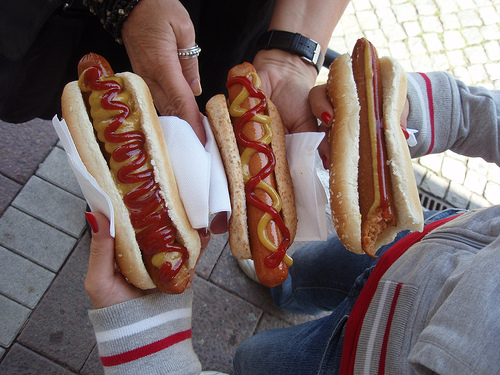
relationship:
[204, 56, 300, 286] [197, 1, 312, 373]
hot dog in middle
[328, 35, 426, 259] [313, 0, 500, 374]
hot dog on right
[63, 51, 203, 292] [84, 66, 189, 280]
hot dog has ketchup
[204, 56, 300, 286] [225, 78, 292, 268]
hot dog has ketchup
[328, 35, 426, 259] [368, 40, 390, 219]
hot dog has ketchup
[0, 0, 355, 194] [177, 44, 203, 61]
person has a ring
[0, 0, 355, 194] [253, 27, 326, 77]
person has a watch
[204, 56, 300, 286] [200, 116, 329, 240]
hot dog on a napkin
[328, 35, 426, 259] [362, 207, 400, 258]
hot dog has a bite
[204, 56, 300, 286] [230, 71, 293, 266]
hot dog has mustard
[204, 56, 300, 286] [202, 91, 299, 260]
hot dog in a bun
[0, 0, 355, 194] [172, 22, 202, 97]
person has a thumb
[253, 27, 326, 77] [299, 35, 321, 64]
watch has a silver buckle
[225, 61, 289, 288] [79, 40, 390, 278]
hot dog have toppings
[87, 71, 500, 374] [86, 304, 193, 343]
sweater has a white stripe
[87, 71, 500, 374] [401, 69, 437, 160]
sweater has stripes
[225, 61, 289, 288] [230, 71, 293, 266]
hot dog have mustard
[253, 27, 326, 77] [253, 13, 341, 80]
watch on a wrist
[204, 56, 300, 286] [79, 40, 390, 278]
hot dog have toppings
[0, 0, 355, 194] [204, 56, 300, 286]
person holding hot dog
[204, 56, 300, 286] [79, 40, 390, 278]
hot dog has toppings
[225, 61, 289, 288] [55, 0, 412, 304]
hot dog are being held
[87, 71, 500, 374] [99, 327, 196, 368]
sweater has a red stripe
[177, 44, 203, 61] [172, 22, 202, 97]
ring on a thumb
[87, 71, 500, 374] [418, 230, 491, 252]
sweater has a zipper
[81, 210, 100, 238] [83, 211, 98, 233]
nail polish on thumb nail